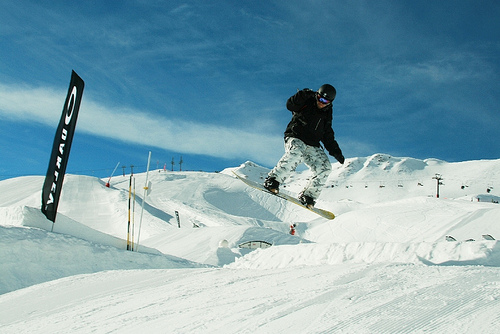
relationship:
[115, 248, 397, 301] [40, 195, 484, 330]
snow on ground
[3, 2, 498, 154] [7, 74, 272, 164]
sky with cloud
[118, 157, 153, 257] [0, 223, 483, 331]
poles sticking from ground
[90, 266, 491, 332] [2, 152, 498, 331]
tracks in ground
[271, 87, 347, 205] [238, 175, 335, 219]
man jumping on snowboard